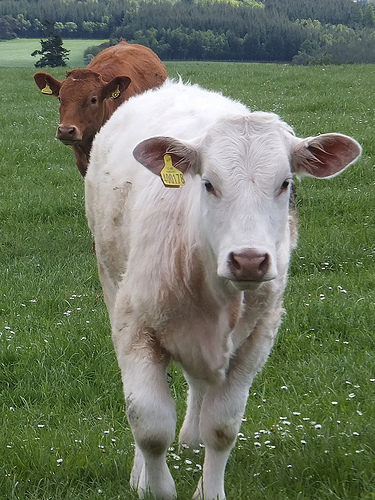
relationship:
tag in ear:
[159, 155, 187, 189] [133, 135, 203, 180]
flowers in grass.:
[250, 398, 338, 455] [271, 66, 371, 135]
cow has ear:
[83, 78, 362, 499] [132, 134, 197, 179]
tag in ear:
[159, 155, 186, 189] [132, 134, 197, 179]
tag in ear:
[39, 80, 53, 95] [30, 71, 60, 96]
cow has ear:
[32, 39, 165, 178] [30, 71, 60, 96]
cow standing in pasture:
[83, 78, 362, 499] [2, 55, 373, 498]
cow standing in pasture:
[32, 39, 165, 178] [2, 55, 373, 498]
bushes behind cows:
[128, 24, 372, 64] [28, 36, 369, 498]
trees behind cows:
[114, 7, 335, 65] [28, 36, 369, 498]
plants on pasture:
[2, 66, 374, 498] [2, 55, 373, 498]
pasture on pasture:
[0, 40, 375, 499] [2, 55, 373, 498]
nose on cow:
[218, 252, 275, 277] [83, 78, 362, 499]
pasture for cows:
[284, 73, 353, 115] [28, 36, 369, 498]